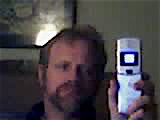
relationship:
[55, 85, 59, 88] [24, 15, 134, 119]
hair on face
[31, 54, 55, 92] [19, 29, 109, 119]
ear on head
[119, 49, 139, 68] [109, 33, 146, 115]
screen on phone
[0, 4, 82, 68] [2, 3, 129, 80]
picture on wall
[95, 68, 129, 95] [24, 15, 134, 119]
thumb of man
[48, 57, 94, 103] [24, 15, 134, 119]
face of man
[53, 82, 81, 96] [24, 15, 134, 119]
mustache of man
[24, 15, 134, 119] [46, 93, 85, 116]
man with beard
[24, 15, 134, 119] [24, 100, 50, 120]
man has tee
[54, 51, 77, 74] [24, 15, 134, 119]
eye of man